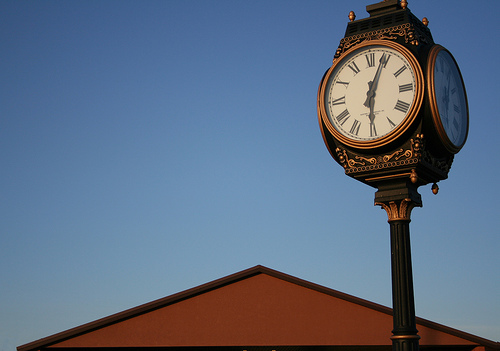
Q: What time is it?
A: 6:04.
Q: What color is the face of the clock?
A: Black and white.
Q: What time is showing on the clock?
A: 6:05.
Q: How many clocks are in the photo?
A: One.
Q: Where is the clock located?
A: On top of ornate metal pole.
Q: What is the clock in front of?
A: Roof of building.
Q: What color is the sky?
A: Blue.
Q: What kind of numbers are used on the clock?
A: Roman numerals.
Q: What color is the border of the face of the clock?
A: Bronze.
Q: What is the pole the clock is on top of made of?
A: Metal.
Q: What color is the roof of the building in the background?
A: Brown.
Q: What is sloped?
A: A building roof.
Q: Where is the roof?
A: Behind the pillar with the clock on it.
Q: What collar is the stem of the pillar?
A: Black.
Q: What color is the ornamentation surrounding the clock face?
A: Gold.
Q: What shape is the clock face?
A: Round.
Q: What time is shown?
A: 6:05.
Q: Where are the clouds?
A: The sky is clear, without clouds.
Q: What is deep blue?
A: The sky.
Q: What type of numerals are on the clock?
A: Roman numerals.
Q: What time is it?
A: 6:05.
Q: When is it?
A: Daytime.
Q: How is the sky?
A: Clear.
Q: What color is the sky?
A: Blue.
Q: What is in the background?
A: A roof.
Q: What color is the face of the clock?
A: White.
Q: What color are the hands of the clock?
A: Black.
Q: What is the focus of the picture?
A: The clock.